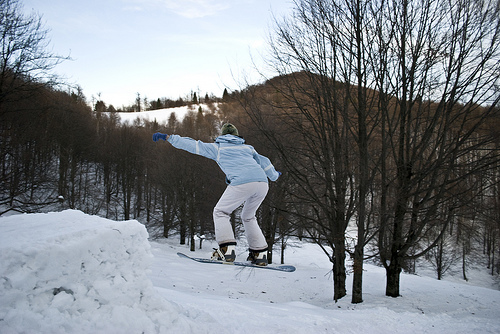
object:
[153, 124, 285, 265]
person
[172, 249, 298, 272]
snowboard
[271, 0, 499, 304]
trees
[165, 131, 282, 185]
jacket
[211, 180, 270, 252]
pants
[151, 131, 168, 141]
glove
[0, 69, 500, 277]
hill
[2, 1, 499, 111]
sky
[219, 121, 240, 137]
hat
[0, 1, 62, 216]
trees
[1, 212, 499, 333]
snow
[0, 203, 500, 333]
ground